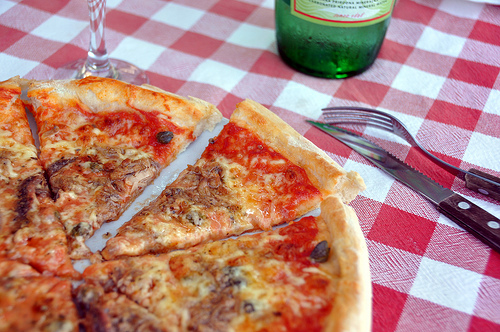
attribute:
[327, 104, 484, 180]
fork — grey, silver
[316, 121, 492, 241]
knife — grey, silver, red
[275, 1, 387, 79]
glass — clear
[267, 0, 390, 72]
bottle — green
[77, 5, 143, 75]
glass — clear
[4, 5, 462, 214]
table — red, white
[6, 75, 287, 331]
pizza — white, cooked, yellow, cheesy, red